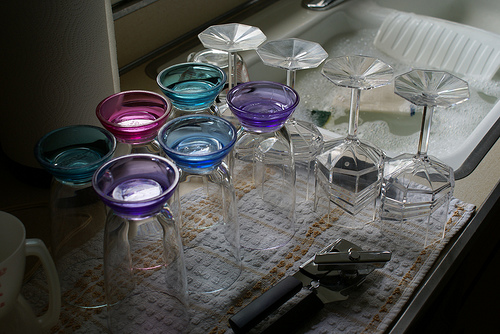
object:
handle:
[229, 274, 319, 334]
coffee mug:
[0, 217, 63, 334]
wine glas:
[373, 67, 469, 251]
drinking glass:
[36, 63, 298, 334]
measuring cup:
[0, 209, 62, 334]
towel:
[23, 137, 476, 334]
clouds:
[36, 23, 472, 334]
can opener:
[228, 239, 391, 334]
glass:
[35, 23, 469, 334]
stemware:
[197, 22, 469, 249]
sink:
[242, 4, 500, 159]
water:
[281, 37, 497, 156]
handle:
[18, 237, 61, 327]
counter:
[0, 0, 499, 334]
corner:
[0, 0, 65, 201]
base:
[37, 62, 300, 218]